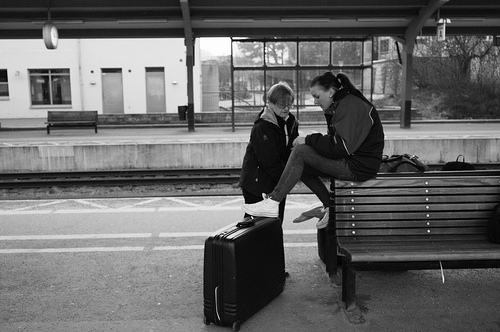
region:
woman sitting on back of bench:
[293, 67, 382, 188]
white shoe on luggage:
[232, 197, 287, 250]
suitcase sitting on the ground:
[187, 214, 297, 326]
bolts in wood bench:
[413, 177, 441, 241]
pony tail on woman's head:
[332, 66, 358, 96]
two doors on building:
[94, 58, 171, 120]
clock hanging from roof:
[37, 29, 65, 54]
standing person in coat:
[225, 80, 302, 213]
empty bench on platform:
[33, 102, 110, 139]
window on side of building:
[20, 63, 77, 114]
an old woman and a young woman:
[157, 61, 402, 322]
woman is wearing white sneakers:
[224, 172, 301, 226]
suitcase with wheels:
[181, 185, 305, 327]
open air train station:
[3, 6, 494, 327]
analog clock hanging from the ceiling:
[35, 11, 85, 60]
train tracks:
[2, 150, 497, 213]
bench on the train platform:
[33, 104, 124, 138]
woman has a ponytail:
[301, 55, 392, 120]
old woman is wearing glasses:
[248, 75, 315, 130]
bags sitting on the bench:
[380, 144, 481, 199]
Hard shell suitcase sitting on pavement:
[193, 211, 288, 329]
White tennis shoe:
[237, 191, 282, 222]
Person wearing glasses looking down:
[254, 81, 301, 161]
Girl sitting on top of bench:
[291, 68, 390, 193]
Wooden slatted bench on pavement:
[331, 170, 497, 315]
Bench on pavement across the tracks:
[36, 108, 108, 134]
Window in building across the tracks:
[25, 59, 77, 114]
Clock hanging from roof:
[36, 9, 62, 56]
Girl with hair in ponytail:
[308, 63, 368, 116]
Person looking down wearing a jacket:
[234, 82, 299, 193]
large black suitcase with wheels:
[204, 211, 288, 327]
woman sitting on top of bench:
[239, 70, 382, 226]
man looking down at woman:
[243, 80, 293, 289]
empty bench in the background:
[43, 110, 103, 135]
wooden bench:
[328, 165, 499, 309]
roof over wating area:
[0, 2, 497, 37]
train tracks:
[1, 165, 240, 198]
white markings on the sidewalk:
[2, 188, 327, 265]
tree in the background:
[387, 27, 499, 124]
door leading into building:
[146, 65, 167, 115]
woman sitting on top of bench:
[192, 63, 409, 325]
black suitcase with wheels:
[180, 203, 311, 328]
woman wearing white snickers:
[215, 64, 402, 236]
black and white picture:
[8, 22, 465, 315]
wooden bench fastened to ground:
[320, 172, 490, 322]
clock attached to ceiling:
[29, 7, 76, 57]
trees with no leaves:
[414, 36, 495, 97]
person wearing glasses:
[229, 84, 307, 198]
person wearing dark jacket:
[231, 75, 299, 212]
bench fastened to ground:
[35, 105, 105, 136]